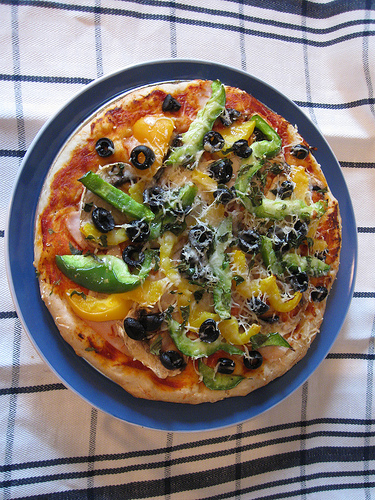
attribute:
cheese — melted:
[54, 156, 302, 324]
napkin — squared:
[10, 6, 112, 69]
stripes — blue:
[2, 5, 367, 496]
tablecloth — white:
[1, 2, 373, 497]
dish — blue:
[234, 49, 316, 120]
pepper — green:
[75, 172, 158, 224]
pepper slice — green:
[81, 166, 170, 231]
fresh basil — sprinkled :
[67, 241, 86, 255]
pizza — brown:
[30, 76, 344, 408]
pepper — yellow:
[130, 110, 178, 181]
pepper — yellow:
[231, 249, 303, 311]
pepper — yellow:
[54, 250, 159, 293]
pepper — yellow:
[79, 170, 155, 222]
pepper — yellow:
[166, 76, 227, 171]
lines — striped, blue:
[291, 5, 327, 18]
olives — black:
[203, 135, 222, 147]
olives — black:
[144, 310, 157, 321]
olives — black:
[125, 313, 134, 330]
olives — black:
[158, 349, 185, 367]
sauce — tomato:
[35, 83, 342, 390]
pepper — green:
[54, 251, 143, 293]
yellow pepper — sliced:
[262, 275, 302, 312]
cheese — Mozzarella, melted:
[149, 175, 211, 230]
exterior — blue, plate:
[75, 60, 272, 115]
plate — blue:
[8, 57, 359, 433]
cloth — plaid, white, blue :
[2, 1, 373, 499]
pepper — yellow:
[123, 110, 178, 185]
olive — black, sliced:
[211, 355, 238, 374]